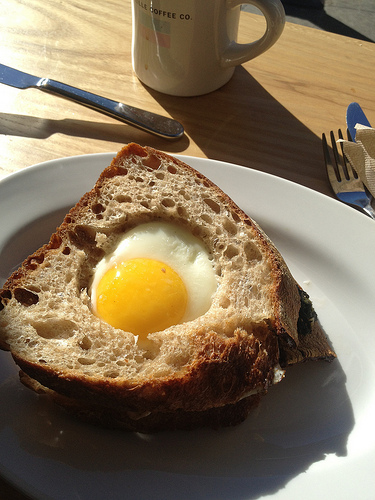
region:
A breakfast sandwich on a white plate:
[2, 137, 326, 449]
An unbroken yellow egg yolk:
[96, 260, 190, 331]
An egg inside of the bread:
[81, 217, 221, 329]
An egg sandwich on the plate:
[9, 141, 334, 428]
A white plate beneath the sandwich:
[316, 215, 366, 310]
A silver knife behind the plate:
[6, 56, 187, 140]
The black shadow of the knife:
[0, 108, 184, 154]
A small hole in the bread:
[32, 313, 80, 347]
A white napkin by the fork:
[340, 120, 373, 189]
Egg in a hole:
[1, 121, 327, 440]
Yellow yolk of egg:
[95, 251, 195, 330]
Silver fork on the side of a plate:
[313, 127, 374, 209]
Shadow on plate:
[203, 437, 302, 478]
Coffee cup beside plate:
[126, 2, 288, 98]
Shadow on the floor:
[305, 4, 359, 24]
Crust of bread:
[267, 258, 338, 366]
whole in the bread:
[142, 156, 162, 172]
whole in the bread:
[202, 197, 220, 216]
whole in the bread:
[224, 246, 239, 260]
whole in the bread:
[242, 247, 259, 265]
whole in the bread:
[166, 353, 185, 370]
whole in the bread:
[76, 355, 96, 366]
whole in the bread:
[76, 334, 92, 351]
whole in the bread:
[29, 315, 78, 344]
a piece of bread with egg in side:
[0, 138, 289, 402]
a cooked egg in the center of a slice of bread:
[79, 210, 199, 321]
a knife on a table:
[0, 61, 181, 132]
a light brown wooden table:
[1, 2, 373, 218]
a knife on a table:
[0, 65, 183, 140]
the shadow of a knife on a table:
[1, 112, 189, 151]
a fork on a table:
[318, 126, 374, 218]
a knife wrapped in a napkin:
[345, 98, 374, 137]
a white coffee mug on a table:
[134, 0, 285, 96]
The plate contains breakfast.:
[0, 131, 370, 422]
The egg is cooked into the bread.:
[12, 140, 348, 456]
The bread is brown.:
[7, 143, 336, 447]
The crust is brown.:
[35, 360, 287, 441]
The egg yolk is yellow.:
[96, 256, 191, 332]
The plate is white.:
[9, 155, 367, 496]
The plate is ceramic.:
[5, 151, 369, 497]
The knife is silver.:
[6, 54, 203, 148]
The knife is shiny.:
[12, 62, 195, 143]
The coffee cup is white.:
[132, 2, 288, 102]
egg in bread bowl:
[100, 224, 218, 326]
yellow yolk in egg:
[99, 261, 180, 325]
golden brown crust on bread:
[176, 358, 268, 423]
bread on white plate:
[12, 152, 342, 430]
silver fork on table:
[319, 124, 374, 205]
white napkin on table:
[342, 124, 374, 180]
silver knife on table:
[1, 61, 182, 141]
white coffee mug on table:
[130, 0, 285, 101]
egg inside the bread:
[95, 206, 217, 321]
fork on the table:
[320, 119, 374, 220]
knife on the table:
[345, 96, 374, 161]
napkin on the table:
[332, 120, 373, 180]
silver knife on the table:
[3, 59, 175, 141]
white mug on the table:
[125, 1, 279, 102]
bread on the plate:
[35, 141, 330, 406]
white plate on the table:
[7, 150, 373, 294]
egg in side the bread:
[91, 224, 202, 324]